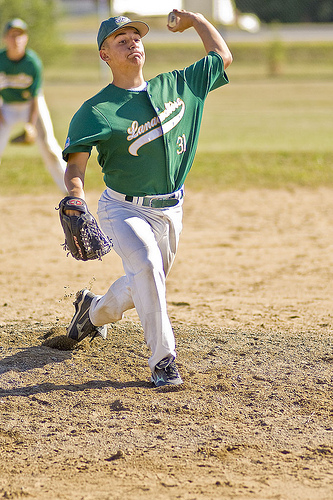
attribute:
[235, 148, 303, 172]
grass — green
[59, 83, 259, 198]
jersey — green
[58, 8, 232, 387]
player — a baseball player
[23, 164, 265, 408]
pants — white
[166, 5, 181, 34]
baseball — white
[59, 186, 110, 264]
glove — black, baseball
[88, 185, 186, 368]
pants — white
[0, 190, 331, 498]
dirt — brown 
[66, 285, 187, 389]
cleats — white, black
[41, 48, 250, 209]
jersey — green short sleve baseball 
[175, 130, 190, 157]
thirtyone — white ,  gold trim 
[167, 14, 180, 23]
stitching — red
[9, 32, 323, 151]
outfield — a baseball outfield